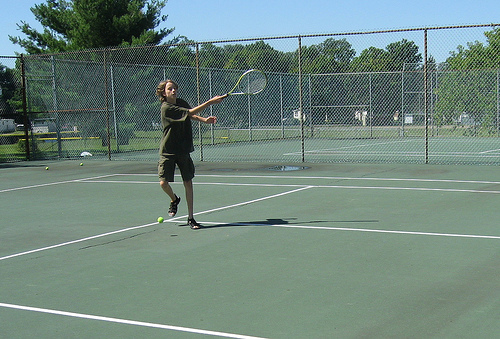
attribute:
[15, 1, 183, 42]
tree — green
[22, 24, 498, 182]
fence — chain link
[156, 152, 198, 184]
shorts — green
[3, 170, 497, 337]
lines — white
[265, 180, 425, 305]
sign — white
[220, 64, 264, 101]
tennis racket — white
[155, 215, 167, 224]
tennis ball — yellow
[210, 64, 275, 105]
racket — tennis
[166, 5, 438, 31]
sky — clear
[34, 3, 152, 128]
tree — tall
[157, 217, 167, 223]
tennis ball — green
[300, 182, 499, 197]
line — white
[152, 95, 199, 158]
shirt — dark green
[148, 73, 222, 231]
boy — playing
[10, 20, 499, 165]
fence — chail link, chain link, metal , Wire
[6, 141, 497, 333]
tennis court — green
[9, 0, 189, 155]
tree — large